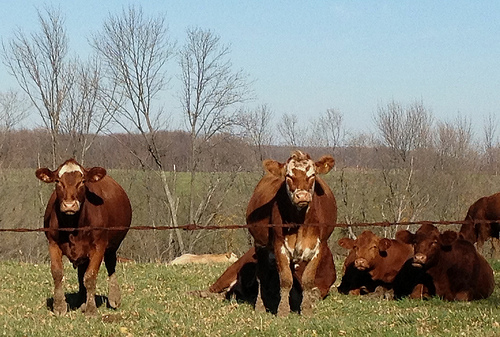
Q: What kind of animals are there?
A: Cows.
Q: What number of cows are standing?
A: 2.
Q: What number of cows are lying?
A: 2.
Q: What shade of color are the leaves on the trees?
A: There are no leaves on the trees.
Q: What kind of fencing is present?
A: Barbed wire.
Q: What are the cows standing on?
A: Grass.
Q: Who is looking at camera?
A: Cows are.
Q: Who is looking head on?
A: Cow is.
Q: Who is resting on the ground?
A: Cow on right.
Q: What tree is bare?
A: Background tree.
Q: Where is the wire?
A: Foreground.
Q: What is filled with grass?
A: The field.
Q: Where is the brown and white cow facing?
A: At the camera.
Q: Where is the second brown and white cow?
A: Next to first cow.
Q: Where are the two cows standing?
A: In the field.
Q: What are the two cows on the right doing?
A: Laying down.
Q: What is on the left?
A: Cow looking towards camera.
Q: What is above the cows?
A: Beautiful blue sky without clouds.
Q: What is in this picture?
A: Group of cows in the field.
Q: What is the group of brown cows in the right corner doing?
A: Laying down.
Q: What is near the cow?
A: Couple of tree branches.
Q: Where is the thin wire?
A: In front of the cows.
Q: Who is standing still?
A: Couple of cows.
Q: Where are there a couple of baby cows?
A: Lying in the grass.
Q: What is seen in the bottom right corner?
A: Two cows sitting on the ground.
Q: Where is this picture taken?
A: A field.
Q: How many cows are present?
A: Five.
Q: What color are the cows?
A: Brown.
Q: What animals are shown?
A: Cows.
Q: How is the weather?
A: Clear.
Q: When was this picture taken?
A: Daytime.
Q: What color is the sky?
A: Blue.